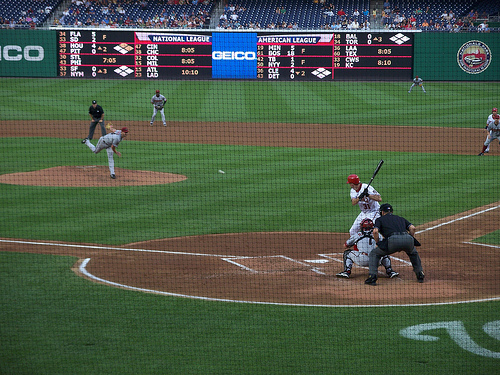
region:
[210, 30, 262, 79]
Blue sign with "GEICO" in white lettering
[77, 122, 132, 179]
Baseball pitcher throwing a baseball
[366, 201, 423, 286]
Umpire watching the play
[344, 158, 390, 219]
Baseball player with black bat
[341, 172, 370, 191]
Baseball player wearing red helmet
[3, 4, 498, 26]
People sitting in stands watching baseball game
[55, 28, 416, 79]
Black stats board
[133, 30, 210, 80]
Stats for National League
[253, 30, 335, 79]
Stats for American League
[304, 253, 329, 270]
Home plate of baseball diamond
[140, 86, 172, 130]
Man wearing gray uniform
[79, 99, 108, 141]
Man wearing black shirt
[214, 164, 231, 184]
Baseball in the air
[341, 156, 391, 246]
Man holding a baseball bat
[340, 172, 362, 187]
Red helmet on man's head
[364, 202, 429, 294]
Man bent over on field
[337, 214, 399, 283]
Man kneeling near ground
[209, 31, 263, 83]
Geico logo on scoreboard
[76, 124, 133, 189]
Man with foot in air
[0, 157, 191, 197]
Brown pile of dirt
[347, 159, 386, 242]
a baseball player holding bat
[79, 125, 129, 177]
a baseball pitcher throwing baseball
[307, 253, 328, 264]
home palte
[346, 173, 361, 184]
a red baseball helmet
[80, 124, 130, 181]
player in grey and red uniform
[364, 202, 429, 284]
baseball umpire leaning over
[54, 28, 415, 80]
a scoreboard built into a wall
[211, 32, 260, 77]
a blue Geico advertisement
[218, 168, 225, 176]
a moving white baseball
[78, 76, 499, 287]
players playing baseball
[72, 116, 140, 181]
person on a baseball field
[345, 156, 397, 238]
person on a baseball field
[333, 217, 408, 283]
person on a baseball field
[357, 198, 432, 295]
person on a baseball field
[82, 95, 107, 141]
person on a baseball field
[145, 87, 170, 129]
person on a baseball field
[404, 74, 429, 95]
person on a baseball field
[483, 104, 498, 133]
person on a baseball field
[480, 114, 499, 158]
person on a baseball field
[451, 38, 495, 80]
logo on a fence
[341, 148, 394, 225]
batter holding a black bat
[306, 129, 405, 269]
batter holding a black bat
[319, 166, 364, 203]
the helmet is red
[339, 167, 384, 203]
the helmet is red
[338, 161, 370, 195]
the helmet is red